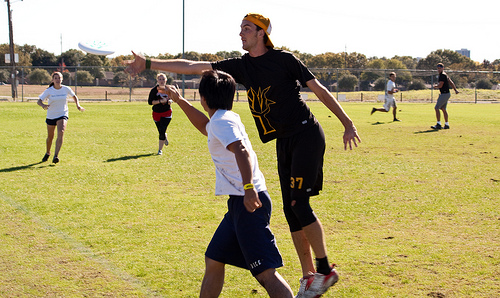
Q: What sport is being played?
A: Frisbee.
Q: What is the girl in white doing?
A: Running towards the Frisbee.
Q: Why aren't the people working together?
A: There's two separate teams.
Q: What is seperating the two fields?
A: A fence.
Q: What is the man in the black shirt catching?
A: A white frisbee.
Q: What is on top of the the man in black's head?
A: An orange hat.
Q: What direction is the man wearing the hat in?
A: Backwards.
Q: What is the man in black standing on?
A: A field.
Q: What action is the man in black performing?
A: Catching a frisbee.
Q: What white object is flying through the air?
A: A frisbee.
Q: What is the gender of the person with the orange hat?
A: Male.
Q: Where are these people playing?
A: On a grass field.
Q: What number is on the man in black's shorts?
A: Thirty-seven.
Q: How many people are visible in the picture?
A: Six.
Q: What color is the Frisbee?
A: White.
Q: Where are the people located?
A: In a field.